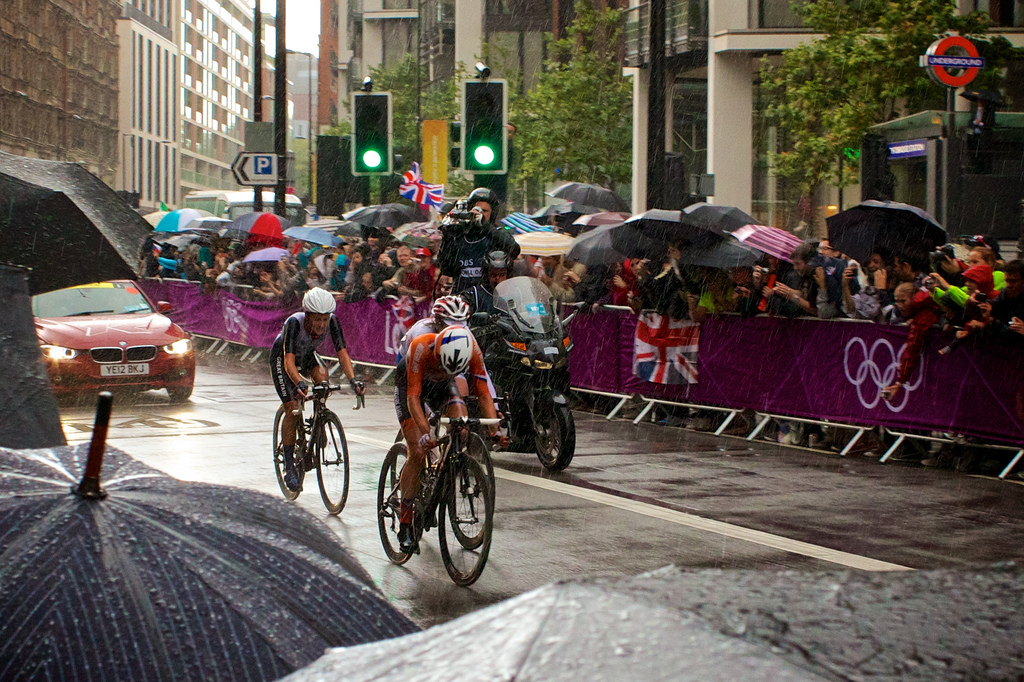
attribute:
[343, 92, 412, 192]
light — black, metal, on, green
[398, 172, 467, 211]
flag — blue, flying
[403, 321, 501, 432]
man — racing, winning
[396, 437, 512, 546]
bike — black, small, moving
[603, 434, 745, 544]
road — wet, black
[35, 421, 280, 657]
umbrella — black, wet, close, soaked